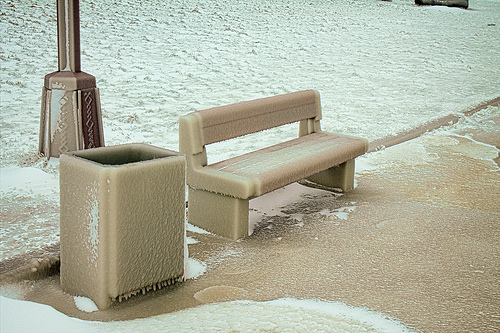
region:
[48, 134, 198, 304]
A trash can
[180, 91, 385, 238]
A park bench is frozen.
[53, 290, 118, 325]
Snow by the trash can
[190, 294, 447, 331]
Snow on the sidewalk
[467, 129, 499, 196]
Ice on the sidewalk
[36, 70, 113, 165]
The base of a light.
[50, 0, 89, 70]
The post of a street light.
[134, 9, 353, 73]
Snow on the grass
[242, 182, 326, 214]
Snow under the bench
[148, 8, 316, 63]
Grass under the snowy hill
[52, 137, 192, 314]
the pail is big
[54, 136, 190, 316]
the pail is tan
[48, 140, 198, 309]
the pail is covered in ice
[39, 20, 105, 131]
the pole is brown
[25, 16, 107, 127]
the pole is behind the bench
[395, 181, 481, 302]
the sidewalk is covered is ice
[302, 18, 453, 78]
the field is covered in a thin layer of snow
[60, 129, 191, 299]
the bench is beside the pail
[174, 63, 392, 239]
the bench is tan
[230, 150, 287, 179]
the bench has ice on it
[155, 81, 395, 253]
bench in the park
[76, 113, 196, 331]
trash can in the park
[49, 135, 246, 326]
trash can covered in snow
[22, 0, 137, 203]
lamp post in the park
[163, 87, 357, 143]
top of the bench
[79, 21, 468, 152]
snowy ground in the park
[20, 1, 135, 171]
lamp post covered in snow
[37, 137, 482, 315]
trash can next to the bench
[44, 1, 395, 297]
lamp post next to the bench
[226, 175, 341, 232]
patch of snow underneath the bench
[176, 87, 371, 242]
a white and brown bench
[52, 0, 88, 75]
a metal lamp post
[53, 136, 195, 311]
a white trash can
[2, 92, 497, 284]
a cement curb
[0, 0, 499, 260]
white snow on the ground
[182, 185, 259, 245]
the leg of a bench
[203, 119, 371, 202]
the seat of a bench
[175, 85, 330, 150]
the back of a bench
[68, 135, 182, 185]
the mouth of a trash can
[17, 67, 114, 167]
the base of a post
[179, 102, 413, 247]
bench is made of plastic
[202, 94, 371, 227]
bench is covered in ice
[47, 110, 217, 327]
trash can is tan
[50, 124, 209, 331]
trash can is covered in ice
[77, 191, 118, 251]
snow on the trash can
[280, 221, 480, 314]
ice on the ground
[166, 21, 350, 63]
snow on the ground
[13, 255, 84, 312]
ice on the street curb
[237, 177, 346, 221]
snow under the bench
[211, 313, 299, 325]
snow on the ice